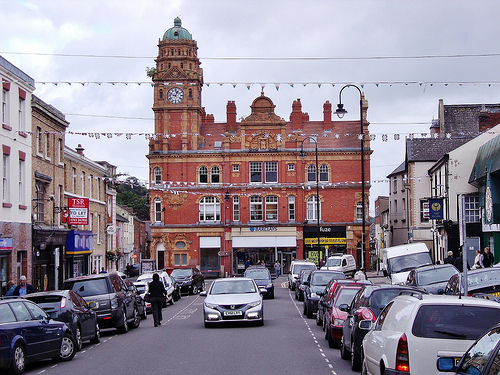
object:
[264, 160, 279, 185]
window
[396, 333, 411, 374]
light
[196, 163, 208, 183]
window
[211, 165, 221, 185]
window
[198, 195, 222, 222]
window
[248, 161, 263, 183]
window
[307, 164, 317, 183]
window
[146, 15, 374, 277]
building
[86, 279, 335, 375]
road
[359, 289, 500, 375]
car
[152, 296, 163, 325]
pants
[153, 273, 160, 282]
hair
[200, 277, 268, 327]
car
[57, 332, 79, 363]
tire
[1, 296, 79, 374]
car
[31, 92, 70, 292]
building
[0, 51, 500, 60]
power line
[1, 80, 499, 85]
power line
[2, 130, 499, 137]
power line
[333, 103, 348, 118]
lamp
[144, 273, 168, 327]
lady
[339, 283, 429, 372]
car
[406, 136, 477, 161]
rooftop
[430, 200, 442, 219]
sign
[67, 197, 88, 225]
banner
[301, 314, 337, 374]
lines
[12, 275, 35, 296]
people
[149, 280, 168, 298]
shirt